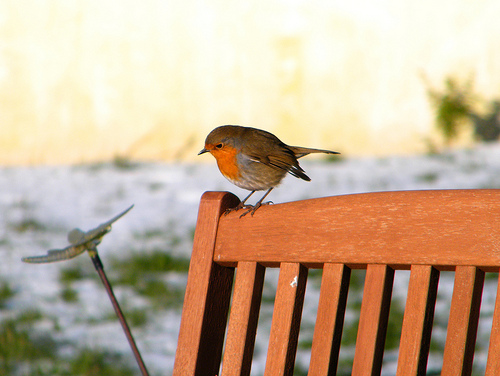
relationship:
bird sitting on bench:
[190, 111, 329, 203] [173, 187, 498, 373]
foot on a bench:
[237, 198, 273, 218] [173, 187, 498, 373]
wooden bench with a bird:
[169, 185, 499, 374] [190, 111, 329, 203]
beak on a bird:
[197, 147, 210, 156] [190, 111, 329, 203]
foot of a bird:
[254, 184, 274, 218] [200, 114, 340, 209]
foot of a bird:
[235, 180, 253, 208] [200, 114, 340, 209]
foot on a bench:
[254, 184, 274, 218] [173, 187, 498, 373]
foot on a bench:
[235, 180, 253, 208] [173, 187, 498, 373]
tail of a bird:
[294, 142, 335, 159] [201, 124, 339, 204]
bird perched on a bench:
[190, 111, 329, 203] [173, 187, 498, 373]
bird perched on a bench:
[190, 111, 329, 203] [108, 171, 495, 361]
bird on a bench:
[190, 111, 329, 203] [173, 187, 498, 373]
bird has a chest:
[190, 111, 329, 203] [210, 146, 237, 178]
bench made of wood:
[173, 171, 495, 373] [171, 184, 497, 372]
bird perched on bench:
[190, 111, 329, 203] [173, 187, 498, 373]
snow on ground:
[25, 164, 171, 224] [3, 158, 497, 373]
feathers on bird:
[267, 143, 311, 179] [190, 111, 329, 203]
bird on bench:
[190, 111, 329, 203] [173, 187, 498, 373]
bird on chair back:
[190, 111, 329, 203] [151, 191, 496, 367]